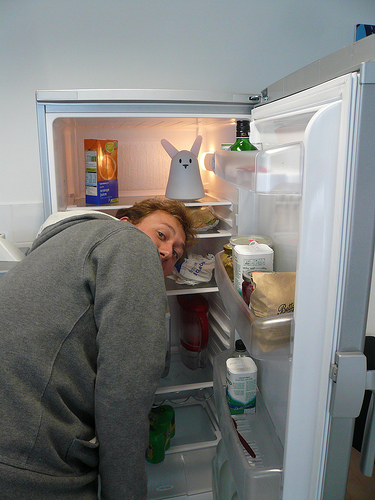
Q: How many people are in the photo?
A: One.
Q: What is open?
A: Fridge.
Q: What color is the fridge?
A: White.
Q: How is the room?
A: Well lit.